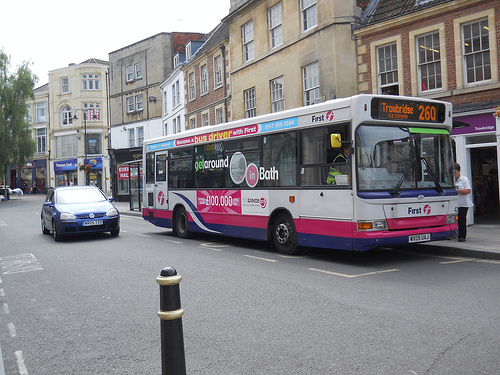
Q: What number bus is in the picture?
A: 260.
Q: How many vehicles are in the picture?
A: Two.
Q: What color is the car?
A: Blue.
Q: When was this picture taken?
A: Daytime.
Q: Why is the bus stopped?
A: Pick up passengers.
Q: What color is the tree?
A: Green.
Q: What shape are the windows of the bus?
A: Square.